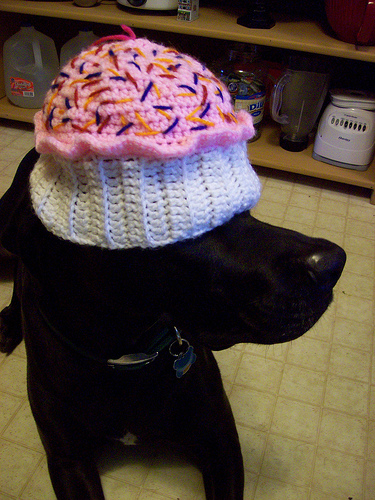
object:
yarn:
[140, 81, 153, 103]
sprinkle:
[153, 105, 174, 109]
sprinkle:
[178, 85, 196, 94]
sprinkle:
[159, 73, 176, 80]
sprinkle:
[184, 116, 215, 127]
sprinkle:
[106, 67, 120, 77]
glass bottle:
[208, 59, 267, 146]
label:
[234, 91, 264, 125]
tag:
[172, 347, 197, 380]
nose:
[294, 238, 347, 291]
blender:
[311, 96, 375, 170]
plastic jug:
[3, 20, 60, 110]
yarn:
[97, 114, 112, 135]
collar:
[37, 316, 170, 373]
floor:
[0, 120, 374, 500]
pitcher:
[268, 69, 334, 152]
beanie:
[27, 22, 261, 253]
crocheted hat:
[33, 23, 254, 161]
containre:
[319, 0, 375, 40]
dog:
[0, 150, 346, 500]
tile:
[276, 362, 330, 409]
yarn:
[135, 131, 160, 137]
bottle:
[59, 30, 101, 68]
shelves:
[0, 0, 375, 204]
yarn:
[124, 68, 140, 93]